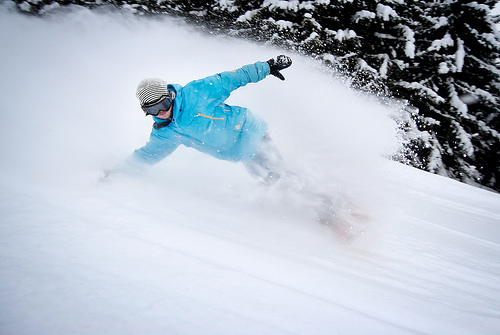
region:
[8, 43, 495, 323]
snow on the ground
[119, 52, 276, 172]
person wearing a blue coat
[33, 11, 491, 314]
the person is sideways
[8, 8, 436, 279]
the person is kicking up snow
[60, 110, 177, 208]
person has hand in snow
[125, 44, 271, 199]
woman wearing blue jacket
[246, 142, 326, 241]
woman wearing white ski pants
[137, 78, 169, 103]
woman wearing white cap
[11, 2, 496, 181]
green evergreen trees dusted with snow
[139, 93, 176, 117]
woman wearing white goggles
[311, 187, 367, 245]
woman wearing white ski boots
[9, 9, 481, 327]
snow covering mountainside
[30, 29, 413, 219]
large puff of snow created by snowboarding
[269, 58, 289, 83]
player is wearing black mittens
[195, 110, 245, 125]
yellow zipper on blue jacket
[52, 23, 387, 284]
a person riding a snowboard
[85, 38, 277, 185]
a light blue coat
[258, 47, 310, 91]
a person's black glove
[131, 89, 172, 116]
a pair of goggles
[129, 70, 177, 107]
a black and white hat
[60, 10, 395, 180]
a spray of snow in the air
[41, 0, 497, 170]
snow covered evergreen trees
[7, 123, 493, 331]
a snow covered hillside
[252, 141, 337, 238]
a pair of ski pants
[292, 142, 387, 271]
a red snowboard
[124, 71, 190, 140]
woman has white hat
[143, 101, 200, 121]
woman is wearing goggles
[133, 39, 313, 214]
woman has blue coat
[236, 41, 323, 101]
woman has black gloves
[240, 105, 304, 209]
woman has black pants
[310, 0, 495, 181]
trees are snow covered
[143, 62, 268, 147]
snow is on coat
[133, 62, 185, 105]
black stripes on hat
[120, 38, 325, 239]
snowboarder with blue jacket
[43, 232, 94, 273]
white snow on hill side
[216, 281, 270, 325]
white snow on hill side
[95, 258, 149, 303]
white snow on hill side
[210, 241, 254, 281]
white snow on hill side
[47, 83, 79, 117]
white snow on hill side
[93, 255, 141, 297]
white snow on hill side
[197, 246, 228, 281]
white snow on hill side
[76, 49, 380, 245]
person gliding nearly horizontally on snow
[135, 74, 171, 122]
cap and goggles over head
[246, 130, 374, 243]
legs and boots under flying snow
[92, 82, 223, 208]
one arm leaning on slope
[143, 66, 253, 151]
man wearing a blue jacket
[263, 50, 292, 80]
man wearing black gloves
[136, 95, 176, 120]
man wearing snow goggles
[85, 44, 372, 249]
man falling in the snow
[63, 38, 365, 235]
man falling in the snow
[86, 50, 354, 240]
man falling in the snow